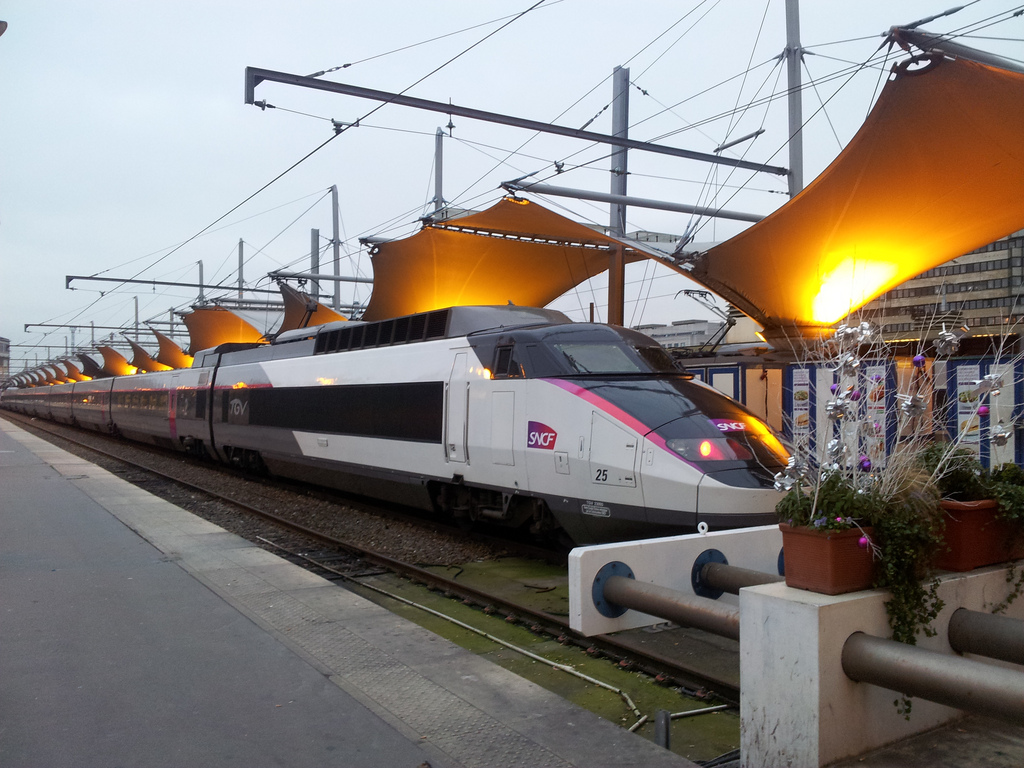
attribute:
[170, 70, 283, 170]
clouds — white 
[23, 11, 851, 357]
sky — blue 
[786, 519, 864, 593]
pot — large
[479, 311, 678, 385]
window — dark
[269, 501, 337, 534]
rock — small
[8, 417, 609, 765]
street — sidewalk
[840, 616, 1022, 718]
pipes — large, metal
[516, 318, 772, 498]
trim — black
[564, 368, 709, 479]
trim — pink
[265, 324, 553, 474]
side — white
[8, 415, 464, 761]
platform — gray